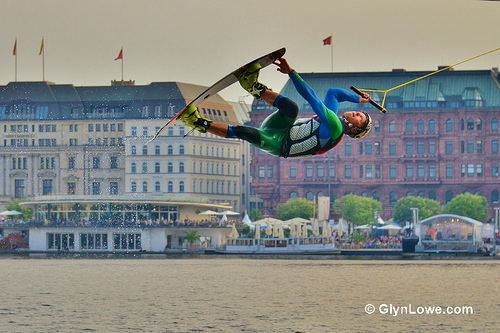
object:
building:
[245, 66, 499, 226]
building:
[0, 78, 253, 224]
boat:
[212, 231, 342, 259]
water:
[1, 252, 499, 332]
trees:
[442, 191, 487, 226]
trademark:
[356, 299, 484, 319]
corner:
[355, 277, 499, 332]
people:
[333, 232, 409, 252]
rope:
[350, 45, 499, 116]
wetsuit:
[207, 69, 359, 160]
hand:
[354, 90, 371, 105]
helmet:
[340, 109, 377, 142]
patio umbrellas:
[198, 206, 403, 245]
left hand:
[271, 55, 298, 75]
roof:
[0, 76, 241, 125]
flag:
[106, 43, 137, 89]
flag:
[316, 33, 340, 73]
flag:
[37, 36, 45, 82]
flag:
[5, 34, 26, 84]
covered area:
[0, 244, 499, 263]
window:
[442, 160, 458, 181]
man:
[172, 50, 377, 161]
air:
[2, 4, 499, 75]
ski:
[143, 43, 292, 145]